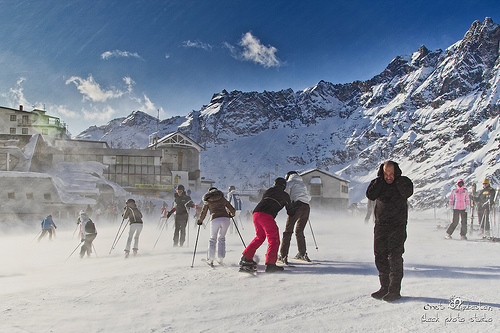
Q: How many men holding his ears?
A: One.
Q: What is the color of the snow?
A: White.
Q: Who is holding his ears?
A: A man.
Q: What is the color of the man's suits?
A: Black.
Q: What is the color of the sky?
A: Blue and white.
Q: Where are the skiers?
A: On the snow.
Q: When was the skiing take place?
A: Daytime.